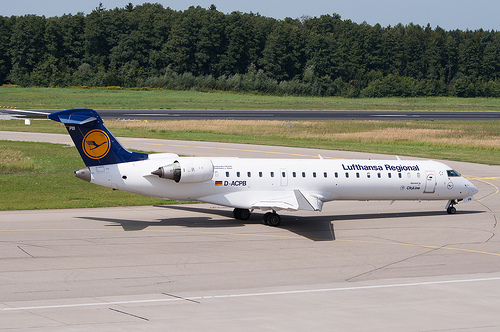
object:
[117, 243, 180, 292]
section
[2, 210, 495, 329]
runway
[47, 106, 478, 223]
aeroplane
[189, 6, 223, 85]
forest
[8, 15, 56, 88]
portion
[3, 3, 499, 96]
plantation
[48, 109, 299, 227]
back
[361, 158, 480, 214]
front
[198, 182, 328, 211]
wing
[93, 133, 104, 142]
yellow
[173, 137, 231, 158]
road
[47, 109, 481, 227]
plane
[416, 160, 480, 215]
head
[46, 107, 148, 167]
tail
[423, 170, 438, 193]
door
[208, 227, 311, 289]
ground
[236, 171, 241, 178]
window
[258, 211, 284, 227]
gear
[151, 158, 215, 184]
engine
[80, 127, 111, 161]
logo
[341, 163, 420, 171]
name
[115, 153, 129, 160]
blue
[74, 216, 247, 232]
shadow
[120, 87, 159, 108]
grass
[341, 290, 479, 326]
tarmac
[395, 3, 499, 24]
sky